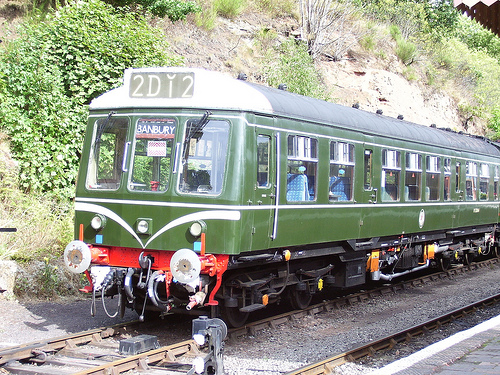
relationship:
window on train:
[175, 116, 228, 200] [72, 60, 498, 322]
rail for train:
[4, 323, 214, 373] [36, 58, 499, 315]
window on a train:
[175, 116, 228, 200] [72, 60, 498, 322]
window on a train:
[175, 113, 236, 200] [72, 60, 498, 322]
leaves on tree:
[68, 40, 96, 70] [0, 0, 174, 190]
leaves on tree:
[28, 112, 80, 145] [0, 0, 174, 190]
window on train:
[329, 143, 357, 163] [72, 60, 498, 322]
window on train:
[377, 149, 402, 169] [72, 60, 498, 322]